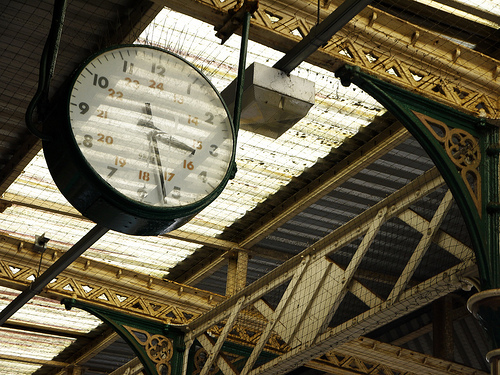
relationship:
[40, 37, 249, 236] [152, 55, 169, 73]
clock has number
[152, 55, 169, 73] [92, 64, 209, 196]
number on clock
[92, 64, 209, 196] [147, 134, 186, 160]
clock has hands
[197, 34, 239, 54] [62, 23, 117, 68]
light from ceiling